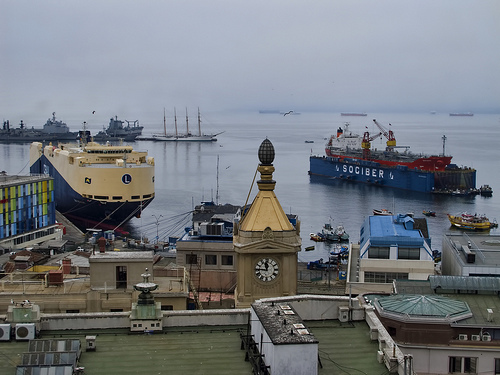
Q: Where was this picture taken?
A: Waterfront.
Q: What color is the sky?
A: Gray.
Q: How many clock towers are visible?
A: One.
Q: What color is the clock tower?
A: Gold.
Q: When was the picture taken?
A: 11:45.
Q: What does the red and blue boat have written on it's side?
A: Sociber.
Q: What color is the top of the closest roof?
A: Green.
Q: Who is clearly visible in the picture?
A: No one.